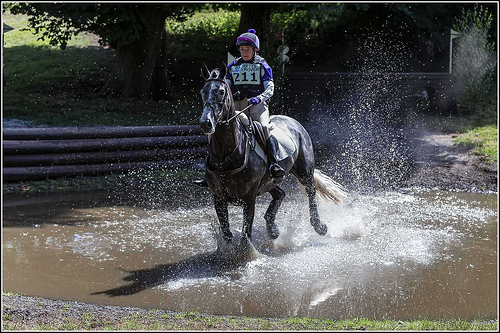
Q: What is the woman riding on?
A: A horse.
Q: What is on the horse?
A: The woman.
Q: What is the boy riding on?
A: A horse.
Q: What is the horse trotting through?
A: Water.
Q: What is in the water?
A: A horse.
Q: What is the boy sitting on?
A: A saddle.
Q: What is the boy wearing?
A: A uniform.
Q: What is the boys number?
A: 211.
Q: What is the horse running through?
A: Water.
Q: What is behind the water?
A: A pathway.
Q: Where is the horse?
A: In a pond.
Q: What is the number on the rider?
A: 211.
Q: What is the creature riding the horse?
A: A human.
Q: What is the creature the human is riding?
A: A horse.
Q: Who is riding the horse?
A: A human.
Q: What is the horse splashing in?
A: Water.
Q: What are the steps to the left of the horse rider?
A: Steps.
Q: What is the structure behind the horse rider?
A: A building.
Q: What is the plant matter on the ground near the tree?
A: Grass.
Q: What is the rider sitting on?
A: A saddle.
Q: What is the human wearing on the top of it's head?
A: A hat.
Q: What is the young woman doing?
A: Riding a horse.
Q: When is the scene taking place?
A: Daytime.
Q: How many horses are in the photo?
A: One.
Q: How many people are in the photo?
A: One.